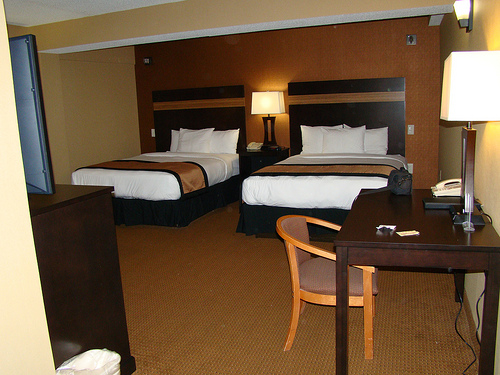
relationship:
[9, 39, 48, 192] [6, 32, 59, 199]
back of television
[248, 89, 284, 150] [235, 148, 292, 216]
lamp on nightstand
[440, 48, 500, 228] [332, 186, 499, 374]
lamp on desk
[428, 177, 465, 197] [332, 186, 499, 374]
phone on desk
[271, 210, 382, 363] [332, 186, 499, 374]
chair by table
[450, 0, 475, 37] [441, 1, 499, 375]
light on wall